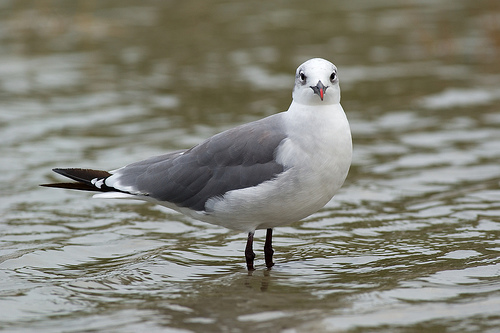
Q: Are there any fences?
A: No, there are no fences.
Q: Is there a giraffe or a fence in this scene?
A: No, there are no fences or giraffes.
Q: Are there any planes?
A: No, there are no planes.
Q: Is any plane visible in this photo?
A: No, there are no airplanes.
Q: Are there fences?
A: No, there are no fences.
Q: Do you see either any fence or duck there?
A: No, there are no fences or ducks.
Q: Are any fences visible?
A: No, there are no fences.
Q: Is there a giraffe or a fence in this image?
A: No, there are no fences or giraffes.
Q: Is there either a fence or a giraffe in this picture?
A: No, there are no fences or giraffes.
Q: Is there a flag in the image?
A: No, there are no flags.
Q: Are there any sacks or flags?
A: No, there are no flags or sacks.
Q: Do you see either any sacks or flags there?
A: No, there are no flags or sacks.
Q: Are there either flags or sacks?
A: No, there are no flags or sacks.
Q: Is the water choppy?
A: Yes, the water is choppy.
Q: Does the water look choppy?
A: Yes, the water is choppy.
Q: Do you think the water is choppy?
A: Yes, the water is choppy.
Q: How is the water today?
A: The water is choppy.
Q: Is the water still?
A: No, the water is choppy.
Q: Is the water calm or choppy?
A: The water is choppy.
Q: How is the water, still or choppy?
A: The water is choppy.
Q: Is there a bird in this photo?
A: Yes, there is a bird.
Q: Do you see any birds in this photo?
A: Yes, there is a bird.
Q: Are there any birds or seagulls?
A: Yes, there is a bird.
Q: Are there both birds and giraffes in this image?
A: No, there is a bird but no giraffes.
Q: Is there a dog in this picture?
A: No, there are no dogs.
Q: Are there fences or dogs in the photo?
A: No, there are no dogs or fences.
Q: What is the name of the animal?
A: The animal is a bird.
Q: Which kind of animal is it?
A: The animal is a bird.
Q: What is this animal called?
A: This is a bird.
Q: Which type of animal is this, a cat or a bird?
A: This is a bird.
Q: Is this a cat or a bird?
A: This is a bird.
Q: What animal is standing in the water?
A: The bird is standing in the water.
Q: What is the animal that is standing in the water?
A: The animal is a bird.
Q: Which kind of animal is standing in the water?
A: The animal is a bird.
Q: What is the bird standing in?
A: The bird is standing in the water.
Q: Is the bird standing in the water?
A: Yes, the bird is standing in the water.